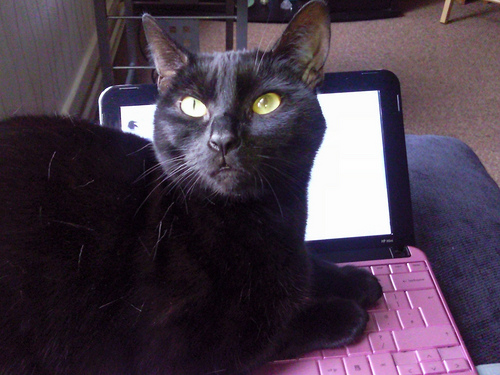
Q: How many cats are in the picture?
A: One.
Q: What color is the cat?
A: Black.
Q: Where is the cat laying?
A: On a laptop.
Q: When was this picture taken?
A: Daytime.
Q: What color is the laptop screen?
A: White.